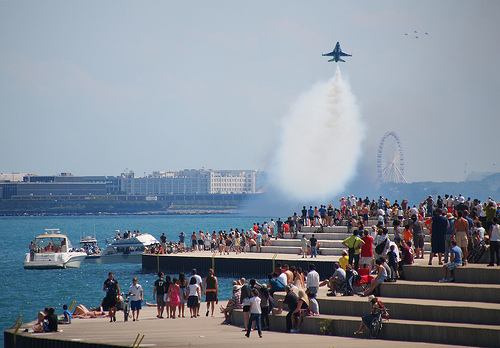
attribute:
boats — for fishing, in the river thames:
[23, 226, 159, 270]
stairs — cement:
[143, 214, 499, 274]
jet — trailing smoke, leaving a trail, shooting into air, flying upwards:
[320, 36, 356, 64]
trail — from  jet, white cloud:
[268, 64, 366, 203]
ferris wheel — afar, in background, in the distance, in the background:
[374, 129, 406, 197]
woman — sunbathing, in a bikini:
[71, 303, 113, 322]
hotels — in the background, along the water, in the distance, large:
[1, 167, 272, 199]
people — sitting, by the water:
[30, 305, 59, 334]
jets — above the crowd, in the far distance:
[402, 27, 431, 42]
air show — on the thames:
[321, 28, 430, 64]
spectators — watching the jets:
[31, 193, 500, 337]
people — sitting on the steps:
[276, 282, 322, 336]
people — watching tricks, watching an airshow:
[145, 194, 500, 270]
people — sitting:
[320, 260, 394, 298]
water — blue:
[2, 215, 294, 347]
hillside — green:
[0, 197, 173, 212]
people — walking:
[151, 268, 220, 321]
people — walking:
[102, 269, 147, 323]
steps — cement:
[228, 261, 499, 347]